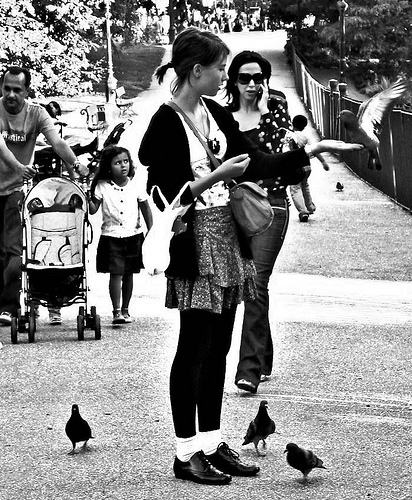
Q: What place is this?
A: It is a street.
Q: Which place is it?
A: It is a street.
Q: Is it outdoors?
A: Yes, it is outdoors.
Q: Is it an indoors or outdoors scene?
A: It is outdoors.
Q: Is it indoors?
A: No, it is outdoors.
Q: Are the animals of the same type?
A: No, there are both pigeons and birds.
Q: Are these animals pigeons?
A: No, there are both pigeons and birds.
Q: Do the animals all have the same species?
A: No, there are both pigeons and birds.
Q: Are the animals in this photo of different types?
A: Yes, they are pigeons and birds.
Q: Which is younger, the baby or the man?
A: The baby is younger than the man.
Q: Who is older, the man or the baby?
A: The man is older than the baby.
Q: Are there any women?
A: Yes, there is a woman.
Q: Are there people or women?
A: Yes, there is a woman.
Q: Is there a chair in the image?
A: No, there are no chairs.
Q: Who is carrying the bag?
A: The woman is carrying the bag.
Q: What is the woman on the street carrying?
A: The woman is carrying a bag.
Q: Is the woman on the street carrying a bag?
A: Yes, the woman is carrying a bag.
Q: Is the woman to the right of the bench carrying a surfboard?
A: No, the woman is carrying a bag.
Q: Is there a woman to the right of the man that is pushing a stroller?
A: Yes, there is a woman to the right of the man.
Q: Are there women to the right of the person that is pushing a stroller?
A: Yes, there is a woman to the right of the man.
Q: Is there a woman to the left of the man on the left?
A: No, the woman is to the right of the man.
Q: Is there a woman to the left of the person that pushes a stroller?
A: No, the woman is to the right of the man.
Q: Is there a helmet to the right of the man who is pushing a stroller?
A: No, there is a woman to the right of the man.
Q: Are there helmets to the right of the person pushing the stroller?
A: No, there is a woman to the right of the man.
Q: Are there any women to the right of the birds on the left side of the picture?
A: Yes, there is a woman to the right of the birds.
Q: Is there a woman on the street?
A: Yes, there is a woman on the street.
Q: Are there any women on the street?
A: Yes, there is a woman on the street.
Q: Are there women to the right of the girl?
A: Yes, there is a woman to the right of the girl.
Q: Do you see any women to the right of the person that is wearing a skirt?
A: Yes, there is a woman to the right of the girl.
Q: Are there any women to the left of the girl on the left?
A: No, the woman is to the right of the girl.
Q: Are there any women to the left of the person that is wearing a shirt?
A: No, the woman is to the right of the girl.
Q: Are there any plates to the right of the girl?
A: No, there is a woman to the right of the girl.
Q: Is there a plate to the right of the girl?
A: No, there is a woman to the right of the girl.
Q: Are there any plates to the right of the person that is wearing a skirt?
A: No, there is a woman to the right of the girl.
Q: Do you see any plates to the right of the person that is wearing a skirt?
A: No, there is a woman to the right of the girl.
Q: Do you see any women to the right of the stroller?
A: Yes, there is a woman to the right of the stroller.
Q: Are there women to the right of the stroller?
A: Yes, there is a woman to the right of the stroller.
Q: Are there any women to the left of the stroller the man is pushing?
A: No, the woman is to the right of the stroller.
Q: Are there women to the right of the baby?
A: Yes, there is a woman to the right of the baby.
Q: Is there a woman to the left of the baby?
A: No, the woman is to the right of the baby.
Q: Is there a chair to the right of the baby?
A: No, there is a woman to the right of the baby.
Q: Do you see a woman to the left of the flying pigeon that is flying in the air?
A: Yes, there is a woman to the left of the pigeon.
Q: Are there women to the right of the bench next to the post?
A: Yes, there is a woman to the right of the bench.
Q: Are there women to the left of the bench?
A: No, the woman is to the right of the bench.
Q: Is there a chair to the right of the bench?
A: No, there is a woman to the right of the bench.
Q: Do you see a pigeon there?
A: Yes, there is a pigeon.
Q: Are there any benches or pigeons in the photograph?
A: Yes, there is a pigeon.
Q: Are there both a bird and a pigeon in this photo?
A: Yes, there are both a pigeon and a bird.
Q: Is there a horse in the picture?
A: No, there are no horses.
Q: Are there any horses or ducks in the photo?
A: No, there are no horses or ducks.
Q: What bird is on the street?
A: The bird is a pigeon.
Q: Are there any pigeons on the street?
A: Yes, there is a pigeon on the street.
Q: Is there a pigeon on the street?
A: Yes, there is a pigeon on the street.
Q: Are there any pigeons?
A: Yes, there is a pigeon.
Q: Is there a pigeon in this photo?
A: Yes, there is a pigeon.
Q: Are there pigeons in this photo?
A: Yes, there is a pigeon.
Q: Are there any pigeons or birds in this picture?
A: Yes, there is a pigeon.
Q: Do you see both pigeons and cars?
A: No, there is a pigeon but no cars.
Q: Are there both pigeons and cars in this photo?
A: No, there is a pigeon but no cars.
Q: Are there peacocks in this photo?
A: No, there are no peacocks.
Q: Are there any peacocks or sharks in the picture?
A: No, there are no peacocks or sharks.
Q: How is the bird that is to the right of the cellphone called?
A: The bird is a pigeon.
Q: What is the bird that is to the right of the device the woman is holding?
A: The bird is a pigeon.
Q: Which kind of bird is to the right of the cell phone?
A: The bird is a pigeon.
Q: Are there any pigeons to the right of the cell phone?
A: Yes, there is a pigeon to the right of the cell phone.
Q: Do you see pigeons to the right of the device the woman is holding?
A: Yes, there is a pigeon to the right of the cell phone.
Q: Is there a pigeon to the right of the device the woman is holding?
A: Yes, there is a pigeon to the right of the cell phone.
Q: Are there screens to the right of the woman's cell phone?
A: No, there is a pigeon to the right of the cellphone.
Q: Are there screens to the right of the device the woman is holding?
A: No, there is a pigeon to the right of the cellphone.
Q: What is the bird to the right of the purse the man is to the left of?
A: The bird is a pigeon.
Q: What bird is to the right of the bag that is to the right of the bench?
A: The bird is a pigeon.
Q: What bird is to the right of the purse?
A: The bird is a pigeon.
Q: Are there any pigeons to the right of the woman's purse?
A: Yes, there is a pigeon to the right of the purse.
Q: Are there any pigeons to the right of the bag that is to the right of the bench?
A: Yes, there is a pigeon to the right of the purse.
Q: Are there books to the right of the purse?
A: No, there is a pigeon to the right of the purse.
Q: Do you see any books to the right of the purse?
A: No, there is a pigeon to the right of the purse.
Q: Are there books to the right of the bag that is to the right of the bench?
A: No, there is a pigeon to the right of the purse.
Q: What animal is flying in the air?
A: The pigeon is flying in the air.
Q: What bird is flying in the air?
A: The bird is a pigeon.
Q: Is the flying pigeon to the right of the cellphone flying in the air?
A: Yes, the pigeon is flying in the air.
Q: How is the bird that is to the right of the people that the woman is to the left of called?
A: The bird is a pigeon.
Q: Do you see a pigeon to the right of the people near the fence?
A: Yes, there is a pigeon to the right of the people.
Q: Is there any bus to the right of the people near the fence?
A: No, there is a pigeon to the right of the people.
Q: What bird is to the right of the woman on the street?
A: The bird is a pigeon.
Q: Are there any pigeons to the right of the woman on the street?
A: Yes, there is a pigeon to the right of the woman.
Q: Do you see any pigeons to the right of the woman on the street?
A: Yes, there is a pigeon to the right of the woman.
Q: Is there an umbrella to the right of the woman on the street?
A: No, there is a pigeon to the right of the woman.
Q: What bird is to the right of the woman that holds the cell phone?
A: The bird is a pigeon.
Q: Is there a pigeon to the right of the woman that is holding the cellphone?
A: Yes, there is a pigeon to the right of the woman.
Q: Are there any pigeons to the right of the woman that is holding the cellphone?
A: Yes, there is a pigeon to the right of the woman.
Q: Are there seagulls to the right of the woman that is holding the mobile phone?
A: No, there is a pigeon to the right of the woman.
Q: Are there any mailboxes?
A: No, there are no mailboxes.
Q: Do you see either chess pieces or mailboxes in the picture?
A: No, there are no mailboxes or chess pieces.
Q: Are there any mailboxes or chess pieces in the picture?
A: No, there are no mailboxes or chess pieces.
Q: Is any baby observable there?
A: Yes, there is a baby.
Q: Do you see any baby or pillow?
A: Yes, there is a baby.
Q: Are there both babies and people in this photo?
A: Yes, there are both a baby and a person.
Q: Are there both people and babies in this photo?
A: Yes, there are both a baby and a person.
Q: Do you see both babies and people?
A: Yes, there are both a baby and a person.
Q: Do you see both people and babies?
A: Yes, there are both a baby and a person.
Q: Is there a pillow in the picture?
A: No, there are no pillows.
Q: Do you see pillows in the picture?
A: No, there are no pillows.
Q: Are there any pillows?
A: No, there are no pillows.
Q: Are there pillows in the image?
A: No, there are no pillows.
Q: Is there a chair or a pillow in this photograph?
A: No, there are no pillows or chairs.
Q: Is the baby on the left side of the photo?
A: Yes, the baby is on the left of the image.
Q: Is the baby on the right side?
A: No, the baby is on the left of the image.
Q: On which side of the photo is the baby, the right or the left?
A: The baby is on the left of the image.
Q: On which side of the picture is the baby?
A: The baby is on the left of the image.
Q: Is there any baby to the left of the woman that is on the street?
A: Yes, there is a baby to the left of the woman.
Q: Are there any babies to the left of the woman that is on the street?
A: Yes, there is a baby to the left of the woman.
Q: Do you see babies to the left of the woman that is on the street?
A: Yes, there is a baby to the left of the woman.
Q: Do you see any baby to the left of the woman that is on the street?
A: Yes, there is a baby to the left of the woman.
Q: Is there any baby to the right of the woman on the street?
A: No, the baby is to the left of the woman.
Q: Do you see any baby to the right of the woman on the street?
A: No, the baby is to the left of the woman.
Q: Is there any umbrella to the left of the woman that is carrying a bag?
A: No, there is a baby to the left of the woman.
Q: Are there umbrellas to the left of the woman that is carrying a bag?
A: No, there is a baby to the left of the woman.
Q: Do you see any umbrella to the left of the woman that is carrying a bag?
A: No, there is a baby to the left of the woman.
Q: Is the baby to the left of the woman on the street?
A: Yes, the baby is to the left of the woman.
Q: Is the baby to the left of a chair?
A: No, the baby is to the left of the woman.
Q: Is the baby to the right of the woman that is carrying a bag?
A: No, the baby is to the left of the woman.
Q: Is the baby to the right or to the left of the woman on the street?
A: The baby is to the left of the woman.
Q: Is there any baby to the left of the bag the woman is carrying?
A: Yes, there is a baby to the left of the bag.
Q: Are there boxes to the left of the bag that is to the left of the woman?
A: No, there is a baby to the left of the bag.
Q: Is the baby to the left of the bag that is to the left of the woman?
A: Yes, the baby is to the left of the bag.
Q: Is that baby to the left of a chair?
A: No, the baby is to the left of the bag.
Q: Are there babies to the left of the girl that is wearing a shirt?
A: Yes, there is a baby to the left of the girl.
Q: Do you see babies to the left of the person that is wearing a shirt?
A: Yes, there is a baby to the left of the girl.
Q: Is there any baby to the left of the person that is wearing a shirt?
A: Yes, there is a baby to the left of the girl.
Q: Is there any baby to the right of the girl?
A: No, the baby is to the left of the girl.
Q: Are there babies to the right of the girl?
A: No, the baby is to the left of the girl.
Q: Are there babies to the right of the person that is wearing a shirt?
A: No, the baby is to the left of the girl.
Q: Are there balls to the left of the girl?
A: No, there is a baby to the left of the girl.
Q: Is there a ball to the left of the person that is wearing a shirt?
A: No, there is a baby to the left of the girl.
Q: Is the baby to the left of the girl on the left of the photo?
A: Yes, the baby is to the left of the girl.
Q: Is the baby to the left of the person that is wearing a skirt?
A: Yes, the baby is to the left of the girl.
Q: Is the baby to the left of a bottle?
A: No, the baby is to the left of the girl.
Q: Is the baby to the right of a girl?
A: No, the baby is to the left of a girl.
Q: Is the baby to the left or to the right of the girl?
A: The baby is to the left of the girl.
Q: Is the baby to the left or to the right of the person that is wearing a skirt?
A: The baby is to the left of the girl.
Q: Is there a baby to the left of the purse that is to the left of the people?
A: Yes, there is a baby to the left of the purse.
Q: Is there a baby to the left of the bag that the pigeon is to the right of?
A: Yes, there is a baby to the left of the purse.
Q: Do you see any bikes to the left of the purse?
A: No, there is a baby to the left of the purse.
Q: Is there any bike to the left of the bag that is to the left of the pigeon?
A: No, there is a baby to the left of the purse.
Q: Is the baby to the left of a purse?
A: Yes, the baby is to the left of a purse.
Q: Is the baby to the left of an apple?
A: No, the baby is to the left of a purse.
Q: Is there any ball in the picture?
A: No, there are no balls.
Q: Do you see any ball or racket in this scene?
A: No, there are no balls or rackets.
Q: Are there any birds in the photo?
A: Yes, there is a bird.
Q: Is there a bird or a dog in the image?
A: Yes, there is a bird.